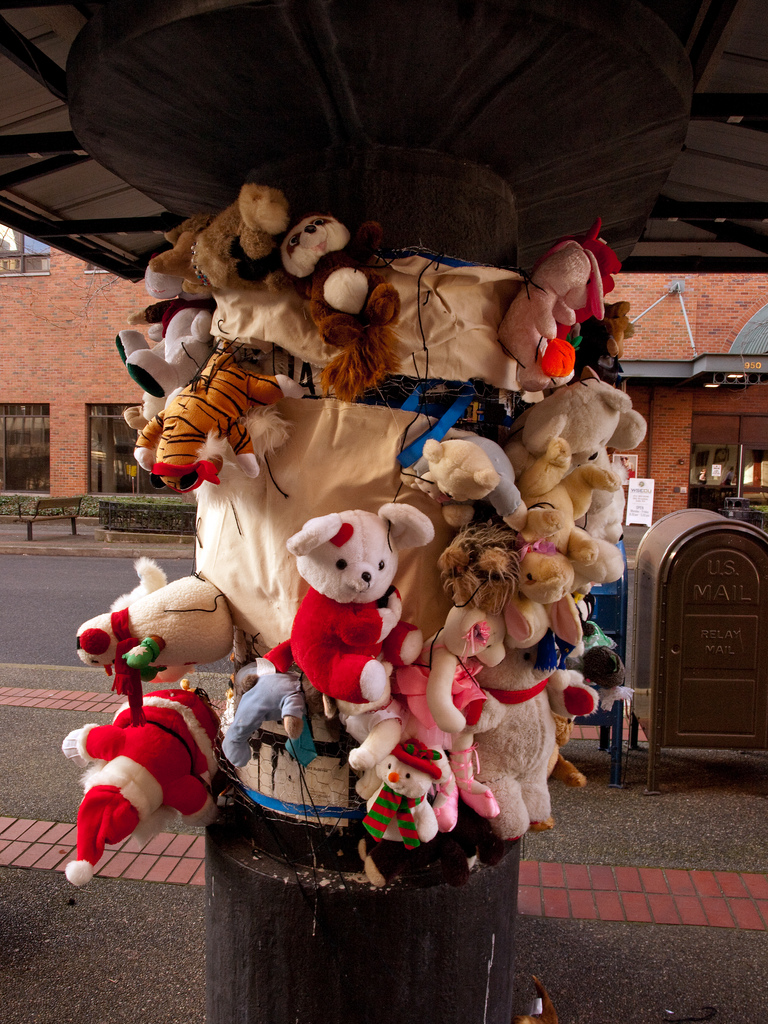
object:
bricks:
[10, 295, 34, 319]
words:
[694, 555, 754, 610]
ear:
[286, 516, 341, 554]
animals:
[281, 208, 399, 380]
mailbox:
[633, 504, 760, 812]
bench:
[0, 496, 83, 537]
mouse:
[272, 503, 432, 701]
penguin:
[71, 569, 234, 682]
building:
[2, 233, 162, 512]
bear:
[284, 210, 389, 394]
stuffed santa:
[57, 684, 222, 882]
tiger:
[145, 343, 284, 478]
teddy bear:
[280, 210, 409, 338]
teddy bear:
[285, 506, 400, 701]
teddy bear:
[405, 430, 520, 528]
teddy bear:
[529, 377, 642, 490]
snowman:
[365, 733, 439, 851]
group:
[54, 176, 655, 891]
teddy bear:
[466, 651, 592, 846]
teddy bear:
[285, 498, 452, 701]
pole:
[293, 142, 518, 263]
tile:
[678, 892, 707, 929]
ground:
[9, 528, 83, 1016]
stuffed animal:
[62, 680, 216, 888]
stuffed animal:
[416, 432, 523, 529]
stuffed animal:
[137, 333, 273, 488]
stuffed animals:
[513, 444, 599, 599]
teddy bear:
[507, 446, 592, 603]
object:
[4, 27, 725, 1015]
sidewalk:
[6, 676, 768, 1015]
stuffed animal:
[368, 737, 441, 841]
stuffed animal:
[283, 504, 425, 698]